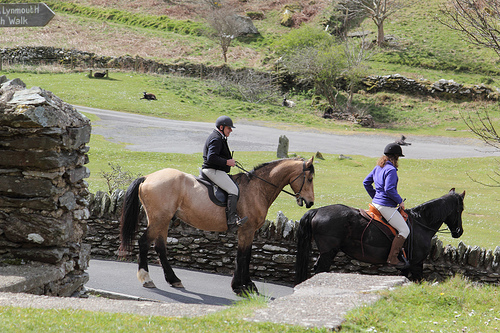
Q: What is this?
A: A nature scene.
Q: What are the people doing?
A: Riding horses.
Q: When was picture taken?
A: During daylight.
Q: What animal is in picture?
A: Horse.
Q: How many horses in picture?
A: Two.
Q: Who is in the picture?
A: People.